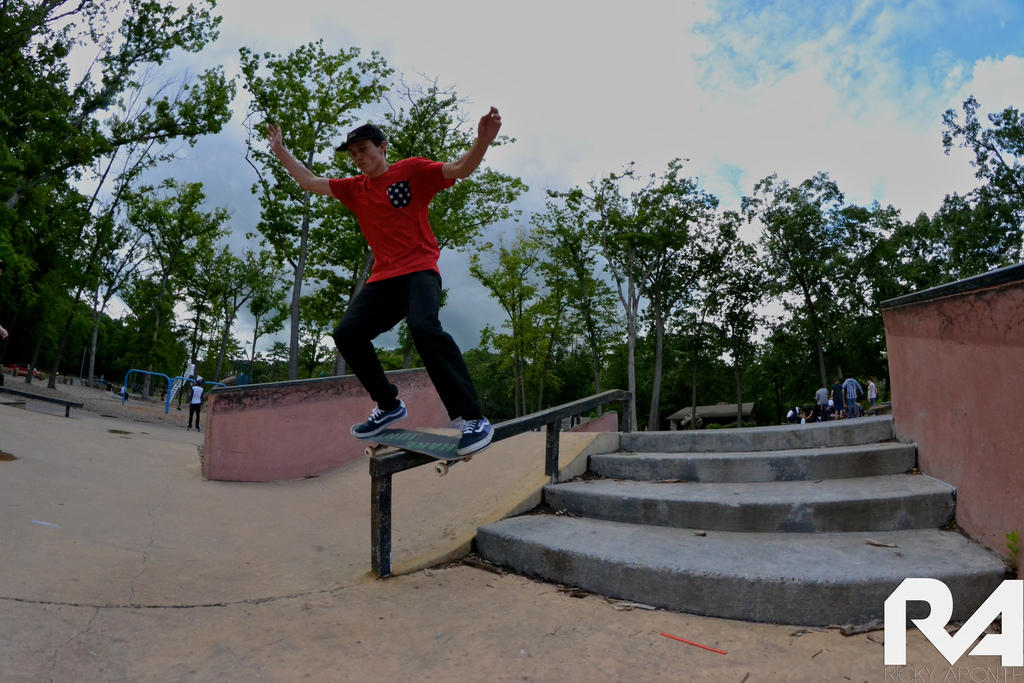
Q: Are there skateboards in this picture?
A: Yes, there is a skateboard.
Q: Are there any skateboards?
A: Yes, there is a skateboard.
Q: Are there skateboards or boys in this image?
A: Yes, there is a skateboard.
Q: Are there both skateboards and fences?
A: No, there is a skateboard but no fences.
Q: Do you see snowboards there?
A: No, there are no snowboards.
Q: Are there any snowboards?
A: No, there are no snowboards.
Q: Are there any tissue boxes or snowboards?
A: No, there are no snowboards or tissue boxes.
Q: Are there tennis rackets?
A: No, there are no tennis rackets.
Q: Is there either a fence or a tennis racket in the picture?
A: No, there are no rackets or fences.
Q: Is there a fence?
A: No, there are no fences.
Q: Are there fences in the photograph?
A: No, there are no fences.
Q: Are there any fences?
A: No, there are no fences.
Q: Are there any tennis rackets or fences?
A: No, there are no fences or tennis rackets.